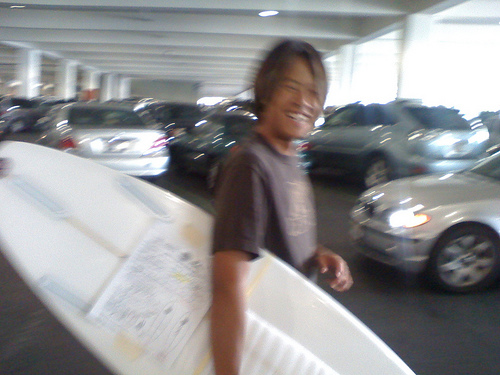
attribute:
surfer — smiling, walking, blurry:
[211, 37, 356, 375]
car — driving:
[349, 146, 498, 296]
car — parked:
[307, 102, 491, 193]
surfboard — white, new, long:
[1, 139, 418, 375]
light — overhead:
[257, 6, 280, 20]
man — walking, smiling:
[208, 39, 354, 374]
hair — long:
[253, 39, 330, 113]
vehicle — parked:
[172, 107, 314, 194]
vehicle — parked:
[41, 100, 172, 182]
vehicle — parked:
[306, 100, 488, 191]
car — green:
[169, 108, 316, 195]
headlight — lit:
[387, 206, 433, 236]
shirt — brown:
[207, 130, 321, 285]